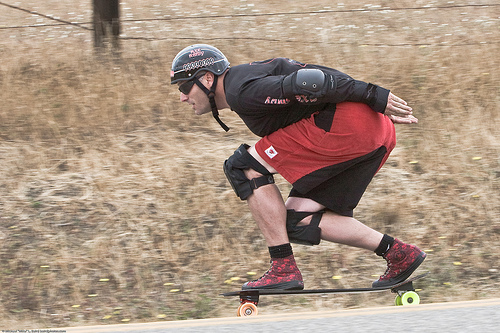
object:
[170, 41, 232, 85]
helmet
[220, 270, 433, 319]
skateboard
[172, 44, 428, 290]
skateboarder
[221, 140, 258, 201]
kneepads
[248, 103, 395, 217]
shorts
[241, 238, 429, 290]
sneakers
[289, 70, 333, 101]
pads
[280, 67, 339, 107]
elbow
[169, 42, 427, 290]
man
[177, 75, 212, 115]
face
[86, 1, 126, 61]
post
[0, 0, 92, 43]
wires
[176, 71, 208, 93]
sunglasses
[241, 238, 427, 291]
shoes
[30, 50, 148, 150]
grass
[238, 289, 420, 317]
wheels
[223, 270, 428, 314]
board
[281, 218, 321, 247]
pad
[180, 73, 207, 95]
glasses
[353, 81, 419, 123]
hands